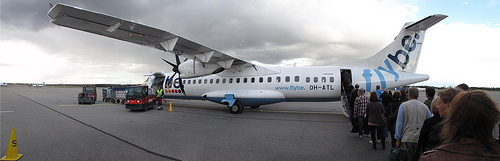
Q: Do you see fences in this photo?
A: No, there are no fences.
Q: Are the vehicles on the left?
A: Yes, the vehicles are on the left of the image.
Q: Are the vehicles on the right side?
A: No, the vehicles are on the left of the image.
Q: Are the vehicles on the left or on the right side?
A: The vehicles are on the left of the image.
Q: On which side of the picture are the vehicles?
A: The vehicles are on the left of the image.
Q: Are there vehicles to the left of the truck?
A: Yes, there are vehicles to the left of the truck.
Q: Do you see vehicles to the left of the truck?
A: Yes, there are vehicles to the left of the truck.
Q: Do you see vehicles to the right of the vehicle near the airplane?
A: No, the vehicles are to the left of the truck.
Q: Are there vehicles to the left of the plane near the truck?
A: Yes, there are vehicles to the left of the airplane.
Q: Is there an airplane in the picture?
A: Yes, there is an airplane.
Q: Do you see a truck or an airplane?
A: Yes, there is an airplane.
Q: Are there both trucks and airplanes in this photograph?
A: Yes, there are both an airplane and a truck.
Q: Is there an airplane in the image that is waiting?
A: Yes, there is an airplane that is waiting.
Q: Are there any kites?
A: No, there are no kites.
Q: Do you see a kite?
A: No, there are no kites.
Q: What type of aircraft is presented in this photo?
A: The aircraft is an airplane.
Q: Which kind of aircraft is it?
A: The aircraft is an airplane.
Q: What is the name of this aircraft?
A: That is an airplane.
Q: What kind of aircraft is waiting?
A: The aircraft is an airplane.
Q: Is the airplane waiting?
A: Yes, the airplane is waiting.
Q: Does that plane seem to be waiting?
A: Yes, the plane is waiting.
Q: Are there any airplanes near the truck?
A: Yes, there is an airplane near the truck.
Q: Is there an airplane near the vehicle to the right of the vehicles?
A: Yes, there is an airplane near the truck.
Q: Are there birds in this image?
A: No, there are no birds.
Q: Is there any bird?
A: No, there are no birds.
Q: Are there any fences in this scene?
A: No, there are no fences.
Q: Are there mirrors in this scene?
A: No, there are no mirrors.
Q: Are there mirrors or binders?
A: No, there are no mirrors or binders.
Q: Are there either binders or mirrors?
A: No, there are no mirrors or binders.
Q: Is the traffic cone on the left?
A: Yes, the traffic cone is on the left of the image.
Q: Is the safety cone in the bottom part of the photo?
A: Yes, the safety cone is in the bottom of the image.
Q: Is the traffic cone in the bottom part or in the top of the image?
A: The traffic cone is in the bottom of the image.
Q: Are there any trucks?
A: Yes, there is a truck.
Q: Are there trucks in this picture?
A: Yes, there is a truck.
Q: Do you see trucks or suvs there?
A: Yes, there is a truck.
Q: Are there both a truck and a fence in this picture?
A: No, there is a truck but no fences.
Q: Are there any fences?
A: No, there are no fences.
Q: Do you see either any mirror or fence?
A: No, there are no fences or mirrors.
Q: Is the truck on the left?
A: Yes, the truck is on the left of the image.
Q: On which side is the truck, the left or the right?
A: The truck is on the left of the image.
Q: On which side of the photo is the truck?
A: The truck is on the left of the image.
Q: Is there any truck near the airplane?
A: Yes, there is a truck near the airplane.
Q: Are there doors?
A: Yes, there is a door.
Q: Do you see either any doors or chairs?
A: Yes, there is a door.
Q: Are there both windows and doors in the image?
A: Yes, there are both a door and windows.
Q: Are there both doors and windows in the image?
A: Yes, there are both a door and windows.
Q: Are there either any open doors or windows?
A: Yes, there is an open door.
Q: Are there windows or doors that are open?
A: Yes, the door is open.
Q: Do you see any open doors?
A: Yes, there is an open door.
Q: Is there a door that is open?
A: Yes, there is a door that is open.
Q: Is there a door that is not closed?
A: Yes, there is a open door.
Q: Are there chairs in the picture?
A: No, there are no chairs.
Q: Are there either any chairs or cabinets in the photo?
A: No, there are no chairs or cabinets.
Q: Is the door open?
A: Yes, the door is open.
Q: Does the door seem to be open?
A: Yes, the door is open.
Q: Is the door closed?
A: No, the door is open.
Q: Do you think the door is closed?
A: No, the door is open.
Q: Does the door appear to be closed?
A: No, the door is open.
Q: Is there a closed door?
A: No, there is a door but it is open.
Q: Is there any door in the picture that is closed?
A: No, there is a door but it is open.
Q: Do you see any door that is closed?
A: No, there is a door but it is open.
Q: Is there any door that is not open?
A: No, there is a door but it is open.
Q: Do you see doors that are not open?
A: No, there is a door but it is open.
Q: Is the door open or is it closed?
A: The door is open.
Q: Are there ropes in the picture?
A: No, there are no ropes.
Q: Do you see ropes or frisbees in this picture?
A: No, there are no ropes or frisbees.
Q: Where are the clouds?
A: The clouds are in the sky.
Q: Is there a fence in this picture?
A: No, there are no fences.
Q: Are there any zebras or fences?
A: No, there are no fences or zebras.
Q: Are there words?
A: Yes, there are words.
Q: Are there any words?
A: Yes, there are words.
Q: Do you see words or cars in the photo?
A: Yes, there are words.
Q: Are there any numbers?
A: No, there are no numbers.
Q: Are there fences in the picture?
A: No, there are no fences.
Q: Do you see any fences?
A: No, there are no fences.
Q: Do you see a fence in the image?
A: No, there are no fences.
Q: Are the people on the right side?
A: Yes, the people are on the right of the image.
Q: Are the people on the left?
A: No, the people are on the right of the image.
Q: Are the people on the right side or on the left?
A: The people are on the right of the image.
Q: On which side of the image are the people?
A: The people are on the right of the image.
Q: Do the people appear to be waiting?
A: Yes, the people are waiting.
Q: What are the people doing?
A: The people are waiting.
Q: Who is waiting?
A: The people are waiting.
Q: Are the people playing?
A: No, the people are waiting.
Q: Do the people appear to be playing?
A: No, the people are waiting.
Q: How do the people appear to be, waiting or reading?
A: The people are waiting.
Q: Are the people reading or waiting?
A: The people are waiting.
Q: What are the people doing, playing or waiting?
A: The people are waiting.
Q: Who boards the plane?
A: The people board the plane.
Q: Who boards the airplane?
A: The people board the plane.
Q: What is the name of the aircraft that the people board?
A: The aircraft is an airplane.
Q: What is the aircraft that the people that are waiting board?
A: The aircraft is an airplane.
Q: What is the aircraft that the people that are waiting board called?
A: The aircraft is an airplane.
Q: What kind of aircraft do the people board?
A: The people board the airplane.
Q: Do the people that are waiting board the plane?
A: Yes, the people board the plane.